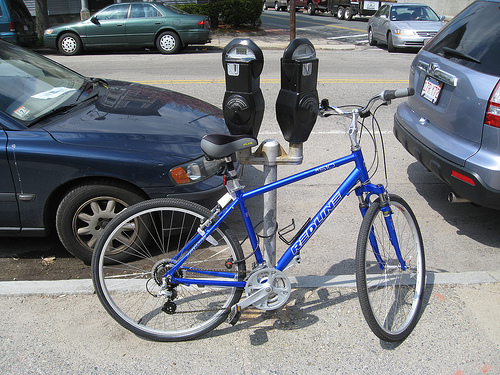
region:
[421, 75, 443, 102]
A tag on the back of a vehicle.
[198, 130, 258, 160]
The seat on a bicycle.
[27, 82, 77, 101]
A piece of paper.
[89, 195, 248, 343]
A tire on a bicycle.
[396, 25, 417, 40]
A headlight on a car.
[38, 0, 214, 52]
A parked car on the street.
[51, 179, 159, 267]
A tire on a vehicle.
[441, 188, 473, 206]
A tailpipe of a vehicle.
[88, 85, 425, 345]
A bicycle on a sidewalk.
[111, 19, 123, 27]
Handle on a car door.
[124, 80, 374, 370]
this is a bike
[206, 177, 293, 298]
the bike is blue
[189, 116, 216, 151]
this is a seat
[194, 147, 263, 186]
the seat is leather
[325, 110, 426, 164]
this is a handlebar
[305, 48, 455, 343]
the handles are silver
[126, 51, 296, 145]
these are parking meters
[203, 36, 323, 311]
two parking meters on a post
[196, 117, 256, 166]
a grey and black bike seat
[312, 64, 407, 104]
yellow lines painted on a street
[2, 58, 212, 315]
a blue car parked next to a curb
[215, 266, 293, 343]
foot peddles on a bicycle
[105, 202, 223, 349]
metal spokes on a bike tire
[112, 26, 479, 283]
two cars parked next to a curb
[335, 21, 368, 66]
white lines painted on a street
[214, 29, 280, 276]
a parking meter on a pole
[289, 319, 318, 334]
shadow on the sidewalk.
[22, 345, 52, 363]
gravel on the sidewalk.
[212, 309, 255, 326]
pedal on the bike.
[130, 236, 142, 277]
spokes on the wheel.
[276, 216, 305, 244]
holder for a water bottle.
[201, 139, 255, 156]
seat on the bike.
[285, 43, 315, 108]
meter on the post.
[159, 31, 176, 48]
tire on the car.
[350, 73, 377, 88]
yellow paint on the road.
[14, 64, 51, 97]
windshield on the car.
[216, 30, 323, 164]
parking meters on the street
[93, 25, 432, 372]
bicycle is next to the parking meters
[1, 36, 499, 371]
the bicycle and parking meters are near two cars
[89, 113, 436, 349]
bicycle is parked on the sidewalk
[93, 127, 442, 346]
the bicycle is blue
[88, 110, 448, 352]
the bicycle is chained to the pole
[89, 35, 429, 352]
the parking meters are near the bicycle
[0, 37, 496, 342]
the cars are parked by the bicycle and parking meters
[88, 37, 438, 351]
the bicycle is leaning against the parking meters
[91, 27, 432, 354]
the parking meters are on a pole near the bicycle